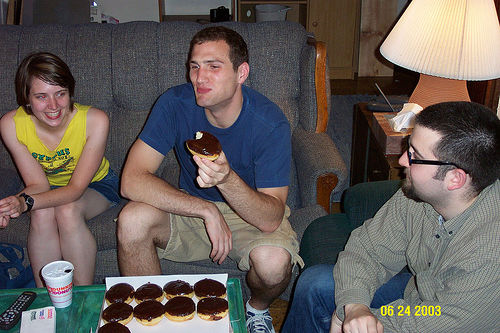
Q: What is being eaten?
A: Donut.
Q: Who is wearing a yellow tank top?
A: The woman.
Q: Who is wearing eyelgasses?
A: A man.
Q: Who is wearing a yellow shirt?
A: A woman.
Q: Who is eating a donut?
A: A man.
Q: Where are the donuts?
A: In a box.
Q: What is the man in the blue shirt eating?
A: A donut.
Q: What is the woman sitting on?
A: A couch.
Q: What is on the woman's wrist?
A: A watch.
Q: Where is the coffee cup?
A: On the table.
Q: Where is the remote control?
A: On a coffee table.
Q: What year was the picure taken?
A: 2003.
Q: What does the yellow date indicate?
A: The date the picture was taken.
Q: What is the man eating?
A: Donut.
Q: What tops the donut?
A: Chocolate.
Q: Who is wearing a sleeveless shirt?
A: The woman.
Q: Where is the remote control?
A: On the table.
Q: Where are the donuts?
A: On the coffee table.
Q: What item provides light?
A: The lamp.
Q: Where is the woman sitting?
A: On the sofa.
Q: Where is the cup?
A: On the coffee table.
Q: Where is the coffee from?
A: Dunkin donuts.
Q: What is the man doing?
A: Eating a donut.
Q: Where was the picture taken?
A: A living room.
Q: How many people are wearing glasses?
A: One.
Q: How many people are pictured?
A: Three.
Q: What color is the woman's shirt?
A: Yellow.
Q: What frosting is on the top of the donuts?
A: Chocolate.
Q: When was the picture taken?
A: 06 24 2003.